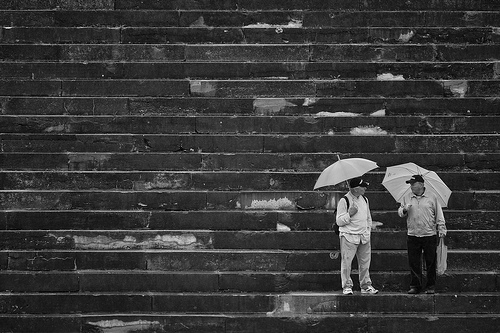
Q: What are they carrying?
A: Umbrellas.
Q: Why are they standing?
A: Motionless.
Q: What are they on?
A: Stairs.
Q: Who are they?
A: People.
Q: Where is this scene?
A: On the stairs.